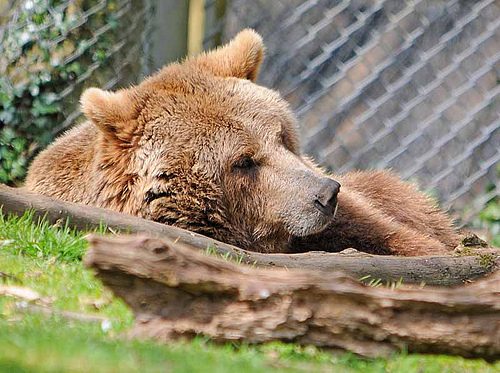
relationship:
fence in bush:
[4, 4, 191, 91] [1, 69, 78, 193]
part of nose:
[322, 182, 341, 217] [310, 175, 344, 217]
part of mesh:
[326, 57, 474, 193] [400, 140, 482, 186]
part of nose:
[322, 182, 349, 217] [312, 166, 348, 218]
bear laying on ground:
[25, 27, 459, 255] [3, 256, 491, 371]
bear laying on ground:
[25, 27, 459, 255] [38, 225, 419, 367]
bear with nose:
[25, 27, 459, 255] [305, 172, 382, 270]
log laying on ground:
[80, 232, 497, 363] [4, 220, 499, 371]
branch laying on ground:
[5, 183, 499, 284] [4, 220, 499, 371]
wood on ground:
[83, 234, 498, 359] [44, 229, 355, 371]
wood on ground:
[1, 182, 499, 286] [44, 229, 355, 371]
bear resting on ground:
[25, 27, 459, 255] [0, 186, 497, 371]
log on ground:
[80, 232, 497, 363] [1, 244, 89, 358]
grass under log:
[0, 204, 499, 371] [0, 182, 499, 289]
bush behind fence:
[3, 0, 150, 190] [44, 15, 157, 201]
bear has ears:
[75, 60, 459, 269] [71, 20, 264, 129]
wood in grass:
[83, 234, 498, 359] [2, 214, 475, 366]